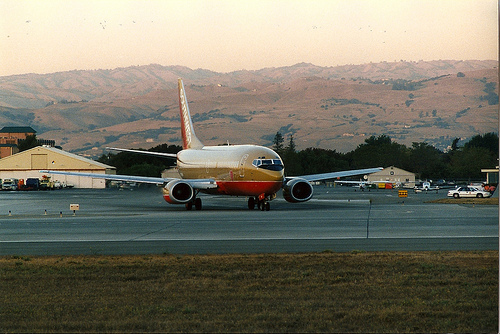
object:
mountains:
[0, 59, 499, 160]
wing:
[282, 167, 384, 204]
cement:
[0, 188, 499, 256]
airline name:
[179, 88, 191, 148]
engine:
[283, 177, 315, 203]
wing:
[38, 170, 218, 205]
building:
[0, 145, 117, 189]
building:
[367, 166, 416, 187]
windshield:
[253, 156, 284, 170]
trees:
[272, 131, 499, 183]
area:
[0, 112, 500, 334]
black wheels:
[185, 198, 202, 211]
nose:
[258, 168, 285, 181]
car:
[447, 185, 492, 199]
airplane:
[39, 77, 384, 211]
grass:
[0, 250, 500, 334]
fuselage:
[177, 144, 285, 196]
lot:
[354, 182, 439, 198]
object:
[8, 210, 12, 216]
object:
[44, 209, 46, 214]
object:
[59, 211, 62, 217]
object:
[70, 203, 80, 216]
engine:
[163, 179, 195, 204]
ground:
[0, 177, 500, 334]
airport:
[0, 180, 496, 257]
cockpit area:
[253, 156, 284, 171]